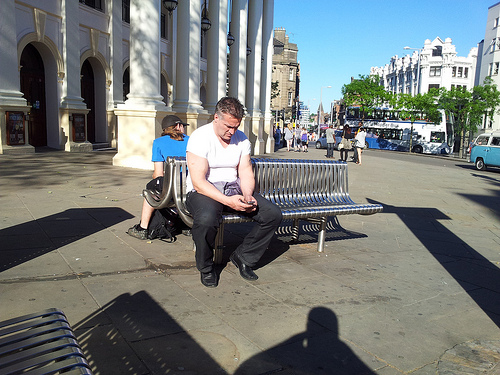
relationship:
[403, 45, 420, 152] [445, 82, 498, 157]
street lamp standing behind tree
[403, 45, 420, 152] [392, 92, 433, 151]
street lamp standing behind tree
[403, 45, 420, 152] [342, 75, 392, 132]
street lamp standing behind tree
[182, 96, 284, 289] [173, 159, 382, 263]
guy sitting on bench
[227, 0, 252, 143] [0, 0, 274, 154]
pillars in front of building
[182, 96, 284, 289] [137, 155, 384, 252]
guy sitting on bench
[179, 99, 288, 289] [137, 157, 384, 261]
guy on a bench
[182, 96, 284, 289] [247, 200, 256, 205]
guy looking at cell phone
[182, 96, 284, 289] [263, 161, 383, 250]
guy sitting bench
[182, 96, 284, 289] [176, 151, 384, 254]
guy sitting down on bench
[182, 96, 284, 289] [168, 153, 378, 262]
guy sitting on bench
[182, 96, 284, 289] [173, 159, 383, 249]
guy sitting down on bench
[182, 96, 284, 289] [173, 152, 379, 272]
guy sitting down on bench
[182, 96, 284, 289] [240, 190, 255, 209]
guy looking at cell phone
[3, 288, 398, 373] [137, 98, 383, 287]
shadow of bench/person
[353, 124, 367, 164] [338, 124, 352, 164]
walking people down walking people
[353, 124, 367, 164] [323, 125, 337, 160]
walking people down walking people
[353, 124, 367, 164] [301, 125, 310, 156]
walking people down walking people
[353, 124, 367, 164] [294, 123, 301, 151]
walking people down walking people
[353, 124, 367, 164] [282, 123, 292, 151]
walking people down walking people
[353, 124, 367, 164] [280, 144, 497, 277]
walking people down street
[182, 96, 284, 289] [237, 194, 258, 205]
guy looking at cell phone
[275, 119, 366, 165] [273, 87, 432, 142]
people walking in background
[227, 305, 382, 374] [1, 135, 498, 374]
shadow on ground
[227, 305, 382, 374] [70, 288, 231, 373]
shadow on shadow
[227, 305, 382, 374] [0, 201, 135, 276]
shadow on shadow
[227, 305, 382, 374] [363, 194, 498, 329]
shadow on shadow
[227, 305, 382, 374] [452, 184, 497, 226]
shadow on shadow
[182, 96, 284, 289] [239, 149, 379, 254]
guy sitting down on bench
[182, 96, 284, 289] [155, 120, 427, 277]
guy sitting down on bench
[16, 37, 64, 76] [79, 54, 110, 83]
arch beside arch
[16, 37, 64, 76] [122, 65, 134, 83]
arch beside arch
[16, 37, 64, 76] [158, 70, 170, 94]
arch beside arch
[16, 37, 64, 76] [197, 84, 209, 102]
arch beside arch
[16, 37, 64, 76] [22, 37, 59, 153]
arch beside doorways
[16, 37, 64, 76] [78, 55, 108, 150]
arch beside entrances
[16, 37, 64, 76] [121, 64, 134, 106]
arch beside entrances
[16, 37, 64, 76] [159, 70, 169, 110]
arch beside entrances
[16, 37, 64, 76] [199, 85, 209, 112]
arch beside entrances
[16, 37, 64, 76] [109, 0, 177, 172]
arch beside pillars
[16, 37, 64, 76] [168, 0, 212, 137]
arch beside pillars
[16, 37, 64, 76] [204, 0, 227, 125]
arch beside pillars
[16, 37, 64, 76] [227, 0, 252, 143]
arch beside pillars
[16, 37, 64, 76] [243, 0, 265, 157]
arch beside pillars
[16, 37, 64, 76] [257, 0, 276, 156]
arch beside pillars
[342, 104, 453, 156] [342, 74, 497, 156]
bus moving behind trees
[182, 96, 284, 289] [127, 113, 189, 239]
guy in person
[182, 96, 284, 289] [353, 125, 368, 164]
guy in person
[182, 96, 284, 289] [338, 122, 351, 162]
guy in person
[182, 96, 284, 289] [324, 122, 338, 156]
guy in person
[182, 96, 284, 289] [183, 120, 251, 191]
guy in shirt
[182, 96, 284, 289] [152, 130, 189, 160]
guy in shirt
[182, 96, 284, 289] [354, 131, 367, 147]
guy in shirt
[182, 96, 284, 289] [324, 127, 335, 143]
guy in shirt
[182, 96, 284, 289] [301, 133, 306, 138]
guy in shirt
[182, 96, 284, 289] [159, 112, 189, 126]
guy in cap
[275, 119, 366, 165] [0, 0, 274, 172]
people near building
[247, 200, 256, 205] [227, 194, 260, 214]
cell phone in mans hands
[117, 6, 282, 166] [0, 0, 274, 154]
pillars in front of building